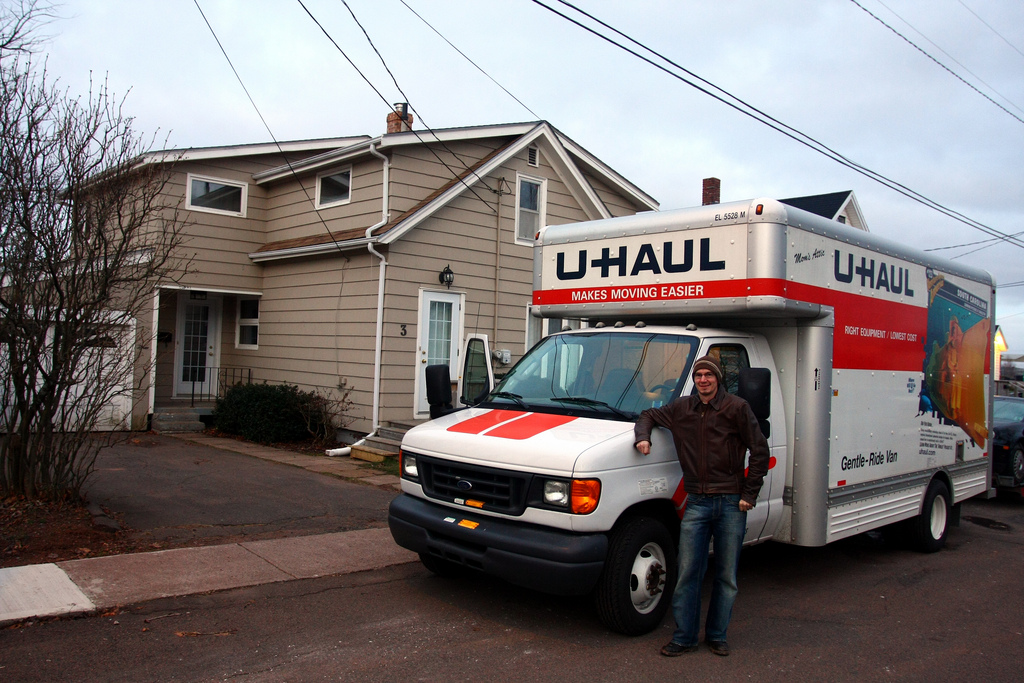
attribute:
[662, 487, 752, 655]
jeans — blue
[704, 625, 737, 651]
shoe — dark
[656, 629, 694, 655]
shoe — dark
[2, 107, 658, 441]
house — tan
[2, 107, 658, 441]
trim — white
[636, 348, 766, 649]
guy — smiling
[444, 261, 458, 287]
light — black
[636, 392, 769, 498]
leather jacket — brown